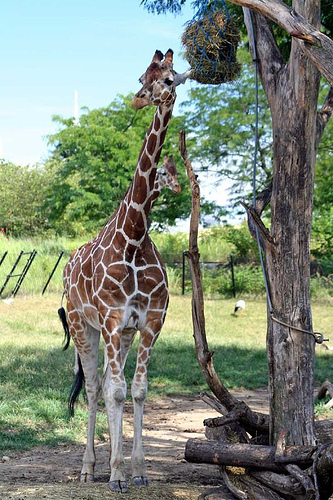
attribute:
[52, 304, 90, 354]
tail — black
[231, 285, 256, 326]
bird — white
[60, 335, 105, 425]
tail — black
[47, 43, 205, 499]
giraffe — brown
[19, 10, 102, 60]
sky — blue color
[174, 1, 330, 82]
leaves — green 